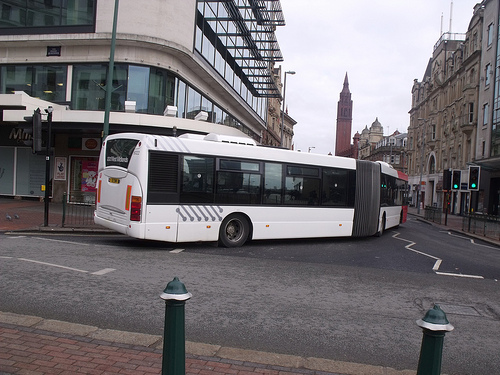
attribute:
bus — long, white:
[70, 91, 419, 252]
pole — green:
[142, 279, 212, 366]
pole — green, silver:
[146, 247, 206, 372]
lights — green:
[444, 160, 484, 198]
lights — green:
[446, 177, 476, 190]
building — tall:
[402, 48, 478, 218]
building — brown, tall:
[400, 31, 483, 203]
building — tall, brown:
[334, 59, 361, 185]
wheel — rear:
[204, 211, 266, 259]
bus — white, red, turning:
[84, 108, 421, 255]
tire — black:
[212, 221, 250, 244]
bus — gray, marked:
[95, 125, 375, 262]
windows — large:
[176, 150, 366, 195]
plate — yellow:
[87, 166, 141, 185]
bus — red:
[342, 160, 442, 236]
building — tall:
[316, 60, 391, 194]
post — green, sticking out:
[115, 270, 238, 372]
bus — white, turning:
[49, 111, 431, 252]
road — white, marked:
[369, 210, 498, 319]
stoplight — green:
[437, 161, 497, 199]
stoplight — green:
[426, 156, 483, 194]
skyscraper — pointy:
[326, 66, 383, 156]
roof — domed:
[351, 115, 396, 136]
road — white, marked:
[27, 235, 186, 315]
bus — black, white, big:
[97, 139, 437, 275]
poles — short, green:
[134, 261, 242, 367]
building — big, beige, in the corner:
[0, 3, 303, 250]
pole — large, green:
[93, 1, 120, 129]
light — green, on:
[459, 178, 479, 196]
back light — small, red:
[125, 191, 146, 223]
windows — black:
[175, 148, 395, 215]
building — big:
[401, 14, 484, 204]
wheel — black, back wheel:
[221, 209, 253, 248]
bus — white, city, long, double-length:
[92, 122, 410, 252]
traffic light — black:
[28, 101, 56, 228]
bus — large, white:
[92, 132, 412, 248]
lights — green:
[449, 180, 478, 189]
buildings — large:
[0, 2, 483, 229]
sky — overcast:
[286, 1, 431, 98]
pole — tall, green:
[99, 0, 125, 136]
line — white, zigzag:
[393, 226, 484, 284]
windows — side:
[181, 153, 355, 208]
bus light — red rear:
[123, 187, 150, 227]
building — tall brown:
[323, 69, 357, 159]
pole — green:
[146, 273, 195, 373]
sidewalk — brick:
[4, 300, 178, 332]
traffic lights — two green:
[440, 160, 485, 238]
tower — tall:
[326, 69, 353, 150]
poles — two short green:
[146, 265, 454, 366]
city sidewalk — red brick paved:
[4, 317, 398, 374]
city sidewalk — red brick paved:
[4, 187, 104, 232]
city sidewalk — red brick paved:
[413, 210, 499, 249]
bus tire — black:
[213, 209, 257, 247]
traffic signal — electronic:
[20, 97, 50, 161]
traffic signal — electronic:
[435, 161, 488, 199]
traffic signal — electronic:
[449, 164, 461, 194]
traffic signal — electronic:
[437, 165, 448, 191]